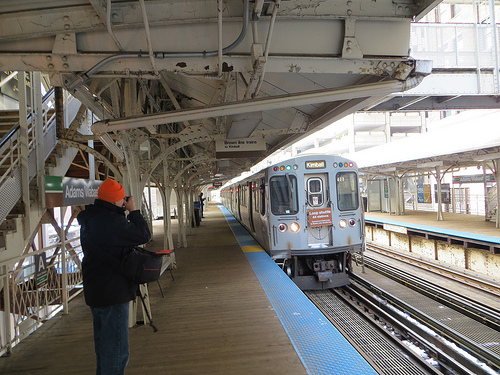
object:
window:
[269, 172, 301, 217]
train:
[217, 152, 367, 293]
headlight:
[289, 221, 301, 234]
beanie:
[97, 177, 125, 203]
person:
[76, 174, 157, 373]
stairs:
[0, 162, 18, 173]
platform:
[0, 204, 378, 375]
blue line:
[215, 200, 377, 375]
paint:
[240, 244, 265, 253]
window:
[335, 170, 360, 212]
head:
[258, 184, 265, 194]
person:
[257, 183, 265, 202]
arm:
[104, 208, 152, 247]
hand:
[123, 195, 136, 211]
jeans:
[89, 302, 133, 374]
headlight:
[338, 218, 348, 228]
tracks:
[387, 294, 499, 362]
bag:
[119, 246, 176, 284]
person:
[198, 192, 206, 218]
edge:
[216, 204, 380, 375]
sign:
[215, 134, 267, 153]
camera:
[122, 195, 130, 205]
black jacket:
[76, 197, 152, 308]